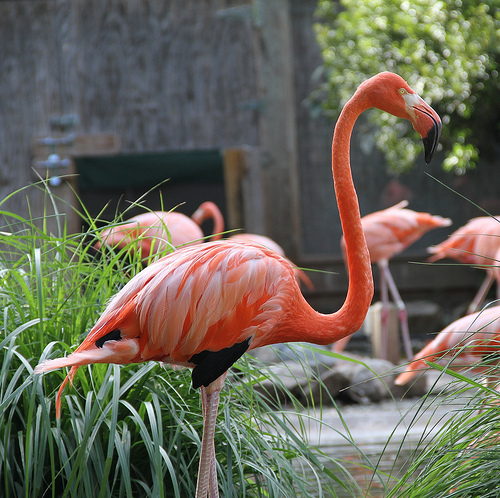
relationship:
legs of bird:
[194, 385, 222, 497] [393, 303, 499, 417]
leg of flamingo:
[377, 276, 389, 366] [334, 197, 454, 369]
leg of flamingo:
[385, 272, 411, 360] [334, 197, 454, 369]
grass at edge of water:
[21, 361, 290, 495] [271, 443, 497, 495]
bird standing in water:
[33, 70, 442, 497] [237, 360, 476, 490]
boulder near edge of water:
[196, 336, 425, 408] [211, 395, 486, 454]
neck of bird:
[331, 100, 374, 341] [225, 45, 436, 280]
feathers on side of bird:
[134, 239, 287, 362] [23, 68, 444, 496]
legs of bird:
[194, 369, 229, 496] [23, 68, 444, 496]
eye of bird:
[400, 87, 405, 92] [23, 68, 444, 496]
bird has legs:
[23, 68, 444, 496] [161, 367, 258, 497]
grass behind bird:
[0, 361, 290, 497] [23, 68, 444, 496]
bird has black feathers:
[23, 68, 444, 496] [188, 336, 250, 388]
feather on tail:
[96, 265, 147, 320] [46, 279, 126, 434]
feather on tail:
[50, 342, 88, 432] [46, 279, 126, 434]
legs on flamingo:
[172, 352, 232, 494] [54, 57, 469, 409]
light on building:
[38, 140, 75, 213] [7, 7, 387, 357]